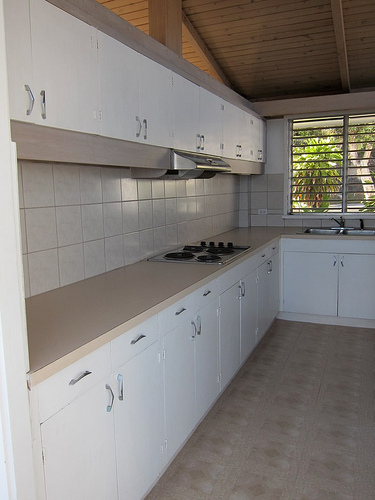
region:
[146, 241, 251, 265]
stovetop set into the counter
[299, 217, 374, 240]
sink on the far counter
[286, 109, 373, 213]
window with slats running across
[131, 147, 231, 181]
vent hood over the stovetop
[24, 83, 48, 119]
handles on the first upper cabinet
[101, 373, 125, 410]
handles on the first lower cabinet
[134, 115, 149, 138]
handles on the second upper cabinet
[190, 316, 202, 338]
handles on the second lower cabinet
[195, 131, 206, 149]
handles above the vent hood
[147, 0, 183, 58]
support beam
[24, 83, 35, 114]
handle on cabinet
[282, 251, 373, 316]
cabinet in the kitchen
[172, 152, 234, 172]
silver range hood on wall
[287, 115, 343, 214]
window on the wall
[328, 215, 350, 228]
faucet on the sink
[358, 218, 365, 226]
water sprayer on the sink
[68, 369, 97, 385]
handle on white drawer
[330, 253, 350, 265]
handles on white cabinet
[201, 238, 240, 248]
cooktop knobs on counter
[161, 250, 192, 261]
burner on cook top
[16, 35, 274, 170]
a row of white cupboards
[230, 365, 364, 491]
a light colored floor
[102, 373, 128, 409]
a pair of silver handles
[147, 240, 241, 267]
four electric stove burners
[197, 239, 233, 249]
a few black knobs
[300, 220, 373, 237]
a stainless steel double sink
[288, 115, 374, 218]
a pair of open blinds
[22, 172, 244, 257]
a white tile wall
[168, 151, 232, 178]
a stainless steel hood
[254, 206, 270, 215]
a white electrical outlet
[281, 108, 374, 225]
Wooden window on the rear wall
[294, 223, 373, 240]
Stainless steel sink on the back wall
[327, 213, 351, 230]
Stainless steel faucet above the sink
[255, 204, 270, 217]
Electrical outlet on the rear wall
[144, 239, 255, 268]
Built in cooktop stove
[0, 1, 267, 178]
White wall cabinets on the left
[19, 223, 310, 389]
Beige counter in the left part of the kitchen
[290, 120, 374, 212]
Trees outside the window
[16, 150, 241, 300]
Beige tile on the left wall of the kitchen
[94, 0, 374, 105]
Wooden slates on the ceiling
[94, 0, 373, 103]
A light colored wooden ceiling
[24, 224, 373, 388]
A beige colored countertop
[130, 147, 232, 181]
A silver range hood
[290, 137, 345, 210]
A tree outside the window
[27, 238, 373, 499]
White colored lower cabinets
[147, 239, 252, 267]
A silver and black stove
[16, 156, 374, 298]
Beige colored backsplash tile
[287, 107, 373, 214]
A window with horizontal blinds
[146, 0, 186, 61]
A wooden pillar in the room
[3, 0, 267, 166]
White colored upper cabinets